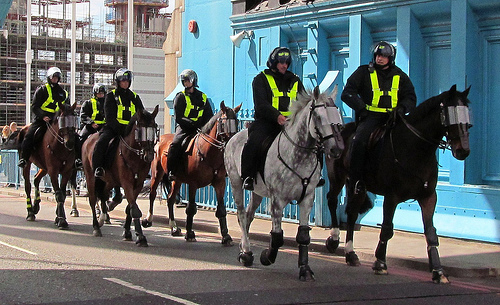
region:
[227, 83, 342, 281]
a white and gray horse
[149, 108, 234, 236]
a brown horse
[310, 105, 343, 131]
head gear on a horse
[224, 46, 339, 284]
a man on a horse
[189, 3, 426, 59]
a sky blue building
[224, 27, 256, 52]
a speaker on a building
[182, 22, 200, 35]
a fire bell on a building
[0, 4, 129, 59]
a building under construction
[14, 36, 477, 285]
a street patrol on horse back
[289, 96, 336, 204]
a harness on a horse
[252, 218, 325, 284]
horses legs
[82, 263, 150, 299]
shadow on the street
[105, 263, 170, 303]
white line in the street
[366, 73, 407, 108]
a vest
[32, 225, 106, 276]
the street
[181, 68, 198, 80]
a grey helmet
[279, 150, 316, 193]
a grey horse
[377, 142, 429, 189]
a brown horse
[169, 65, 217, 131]
man riding a horse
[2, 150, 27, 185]
a gate that is blue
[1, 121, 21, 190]
a couple standing behind a gate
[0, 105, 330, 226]
a teal blue gate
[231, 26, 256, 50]
white loud speaker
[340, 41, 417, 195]
a man in a helmet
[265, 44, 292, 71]
a black and yellow helmet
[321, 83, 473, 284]
a dark brown horse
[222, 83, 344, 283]
a white spotted horse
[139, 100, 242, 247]
a light brown horse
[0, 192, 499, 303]
a paved road cast with shadows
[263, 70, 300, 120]
a yellow reflective vest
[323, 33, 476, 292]
policeman on black horse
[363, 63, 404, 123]
neon yellow safety vest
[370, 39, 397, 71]
black riot helmet on head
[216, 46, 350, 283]
policeman on white horse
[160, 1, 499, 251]
blue building in background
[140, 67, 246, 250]
policeman on ginger horse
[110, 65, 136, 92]
riot helmet with shield pushed up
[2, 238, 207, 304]
white lane separator on street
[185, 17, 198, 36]
round red attachment on wall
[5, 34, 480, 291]
row of policemen riding horses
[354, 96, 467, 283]
horse on the road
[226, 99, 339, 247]
horse on the road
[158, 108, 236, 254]
horse on the road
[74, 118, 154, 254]
horse on the road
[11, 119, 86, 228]
horse on the road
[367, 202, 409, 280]
leg of the horse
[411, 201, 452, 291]
leg of the horse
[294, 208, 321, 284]
leg of the horse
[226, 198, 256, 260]
leg of the horse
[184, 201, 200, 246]
leg of the horse